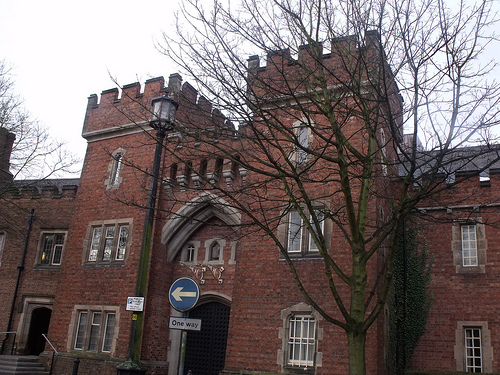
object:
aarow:
[168, 278, 199, 312]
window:
[277, 304, 319, 371]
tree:
[89, 0, 499, 375]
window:
[291, 117, 314, 166]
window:
[103, 147, 128, 187]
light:
[148, 89, 180, 133]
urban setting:
[0, 0, 500, 375]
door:
[23, 303, 56, 357]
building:
[0, 28, 500, 374]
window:
[281, 200, 327, 258]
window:
[459, 222, 479, 267]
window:
[85, 217, 128, 262]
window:
[208, 239, 222, 261]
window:
[461, 323, 481, 373]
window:
[182, 241, 194, 261]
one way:
[168, 318, 203, 331]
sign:
[166, 275, 200, 310]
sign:
[168, 315, 203, 332]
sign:
[126, 296, 145, 312]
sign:
[131, 313, 137, 320]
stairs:
[0, 352, 48, 374]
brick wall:
[0, 198, 79, 354]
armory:
[1, 0, 498, 373]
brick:
[93, 190, 123, 210]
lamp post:
[126, 130, 168, 359]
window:
[73, 310, 113, 356]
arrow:
[169, 287, 197, 302]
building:
[89, 171, 338, 362]